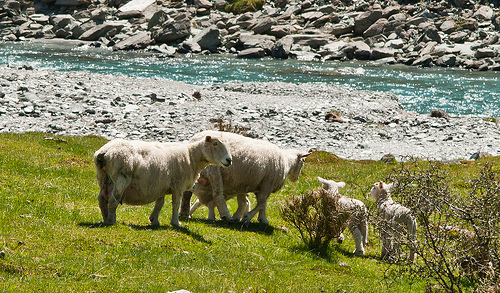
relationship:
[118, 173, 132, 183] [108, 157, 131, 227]
spots on legs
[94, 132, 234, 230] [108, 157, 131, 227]
sheep has legs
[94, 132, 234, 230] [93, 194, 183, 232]
sheep has feet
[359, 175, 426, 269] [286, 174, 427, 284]
sheep on grass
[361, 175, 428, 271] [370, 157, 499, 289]
baby behind brush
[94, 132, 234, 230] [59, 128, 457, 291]
sheep in grass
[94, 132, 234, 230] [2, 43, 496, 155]
sheep head river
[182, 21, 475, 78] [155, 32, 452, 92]
rocks near water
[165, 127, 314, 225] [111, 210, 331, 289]
sheep near grass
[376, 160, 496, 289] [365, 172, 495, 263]
trees near bushes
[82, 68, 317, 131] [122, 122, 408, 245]
beach near family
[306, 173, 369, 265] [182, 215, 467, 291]
sheep near grass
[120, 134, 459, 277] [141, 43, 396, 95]
sheep near water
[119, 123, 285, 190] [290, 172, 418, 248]
sheep near lambs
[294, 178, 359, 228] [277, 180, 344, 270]
lamb behind bush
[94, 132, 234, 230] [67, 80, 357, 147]
sheep near bank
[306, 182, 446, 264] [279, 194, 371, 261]
sheep near shrub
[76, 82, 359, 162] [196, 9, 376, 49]
bank near rocks